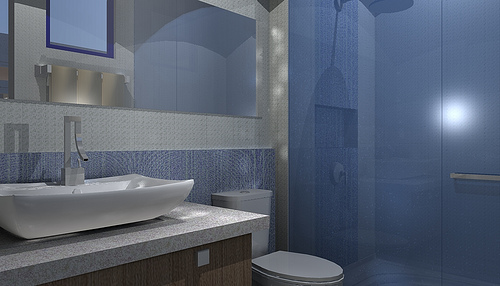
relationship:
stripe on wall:
[2, 101, 283, 150] [0, 0, 287, 249]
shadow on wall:
[1, 120, 38, 180] [0, 0, 287, 249]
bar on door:
[445, 170, 497, 184] [442, 0, 499, 281]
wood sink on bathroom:
[68, 233, 252, 284] [10, 5, 488, 272]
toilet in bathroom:
[210, 186, 347, 284] [10, 5, 488, 272]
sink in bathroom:
[11, 103, 195, 241] [10, 5, 488, 272]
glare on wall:
[422, 89, 478, 136] [385, 70, 454, 177]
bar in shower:
[445, 170, 497, 184] [330, 24, 488, 273]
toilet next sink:
[210, 186, 347, 284] [0, 170, 198, 244]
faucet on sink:
[57, 106, 94, 181] [2, 144, 219, 247]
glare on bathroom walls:
[432, 94, 479, 136] [372, 0, 500, 286]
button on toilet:
[232, 184, 257, 194] [209, 182, 356, 280]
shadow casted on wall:
[15, 0, 257, 61] [1, 2, 374, 272]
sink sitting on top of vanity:
[0, 172, 195, 242] [6, 212, 296, 284]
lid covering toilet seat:
[251, 247, 344, 282] [247, 236, 348, 283]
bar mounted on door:
[445, 170, 497, 184] [270, 0, 500, 286]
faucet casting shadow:
[60, 114, 90, 187] [2, 119, 42, 186]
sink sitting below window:
[0, 172, 195, 242] [46, 0, 114, 57]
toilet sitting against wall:
[210, 186, 347, 284] [2, 2, 272, 188]